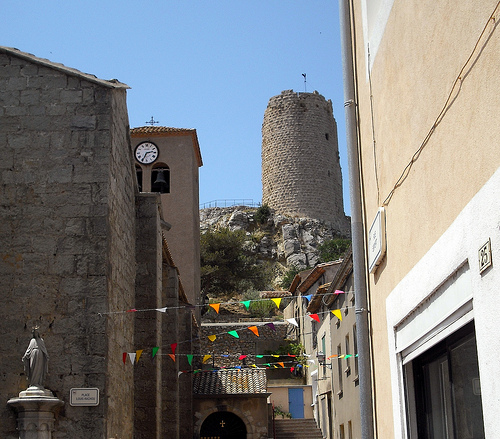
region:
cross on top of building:
[144, 115, 160, 126]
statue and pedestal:
[6, 324, 64, 437]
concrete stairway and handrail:
[269, 400, 324, 437]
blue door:
[286, 384, 306, 418]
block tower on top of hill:
[260, 88, 345, 223]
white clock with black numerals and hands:
[132, 140, 159, 162]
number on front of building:
[476, 238, 493, 275]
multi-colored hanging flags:
[115, 286, 354, 377]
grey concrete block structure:
[0, 41, 199, 436]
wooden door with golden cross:
[201, 411, 246, 437]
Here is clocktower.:
[135, 107, 167, 165]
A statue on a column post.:
[13, 323, 63, 397]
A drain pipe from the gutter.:
[335, 0, 412, 431]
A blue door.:
[285, 379, 312, 416]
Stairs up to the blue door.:
[269, 411, 321, 436]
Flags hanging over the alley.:
[122, 289, 363, 374]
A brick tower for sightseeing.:
[254, 71, 343, 225]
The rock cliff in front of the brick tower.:
[199, 71, 347, 273]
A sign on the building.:
[68, 383, 108, 410]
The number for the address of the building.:
[472, 241, 497, 265]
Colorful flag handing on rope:
[119, 301, 142, 327]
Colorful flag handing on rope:
[149, 297, 181, 319]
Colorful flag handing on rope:
[207, 295, 229, 322]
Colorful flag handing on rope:
[232, 295, 257, 317]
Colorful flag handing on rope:
[263, 285, 290, 303]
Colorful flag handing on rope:
[291, 283, 315, 306]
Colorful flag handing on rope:
[325, 282, 350, 298]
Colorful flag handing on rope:
[120, 345, 145, 360]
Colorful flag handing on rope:
[142, 335, 202, 367]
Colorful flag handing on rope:
[204, 345, 288, 370]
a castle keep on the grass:
[260, 73, 347, 233]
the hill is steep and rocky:
[204, 192, 356, 305]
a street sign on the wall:
[58, 385, 106, 407]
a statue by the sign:
[12, 322, 59, 437]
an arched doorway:
[190, 406, 259, 438]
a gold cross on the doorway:
[215, 416, 228, 432]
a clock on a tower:
[133, 134, 164, 168]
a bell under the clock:
[150, 159, 175, 190]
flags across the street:
[112, 281, 364, 373]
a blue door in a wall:
[278, 382, 310, 417]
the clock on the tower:
[135, 141, 158, 163]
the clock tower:
[129, 127, 204, 325]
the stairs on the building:
[269, 416, 323, 437]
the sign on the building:
[67, 387, 98, 405]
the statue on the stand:
[19, 324, 53, 396]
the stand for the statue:
[6, 396, 63, 437]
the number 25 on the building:
[477, 240, 492, 274]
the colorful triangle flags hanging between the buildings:
[97, 288, 360, 372]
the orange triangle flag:
[209, 300, 221, 313]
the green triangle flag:
[240, 299, 250, 310]